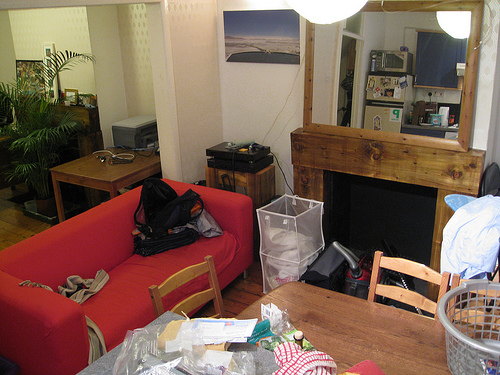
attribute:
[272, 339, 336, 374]
was cloth — white, red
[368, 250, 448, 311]
chair — wooden, brown, woode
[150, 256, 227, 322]
chair — wooden, brown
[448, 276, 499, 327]
chair — wooden, brown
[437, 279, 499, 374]
laundry basket — gray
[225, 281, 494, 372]
table — wooden, woode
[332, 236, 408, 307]
vacume — gray, red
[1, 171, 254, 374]
couch — red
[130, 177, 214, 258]
stuff — black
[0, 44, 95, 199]
plant — green, bushy, big, gree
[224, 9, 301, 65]
picture — hanging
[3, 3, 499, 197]
wall — white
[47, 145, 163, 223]
table — brown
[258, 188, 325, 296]
hamper — white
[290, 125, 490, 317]
fireplace — woode, framed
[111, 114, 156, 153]
printer — white, grey